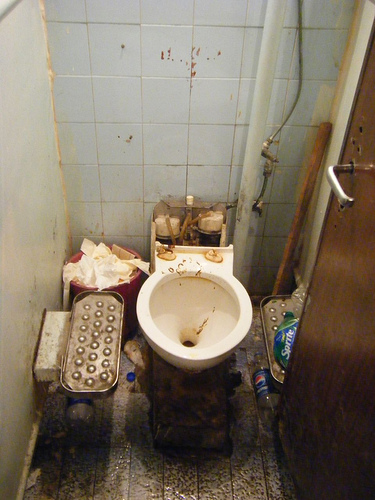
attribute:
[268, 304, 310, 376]
sprite bottle — empty 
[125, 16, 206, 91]
wall tile — old , dirty 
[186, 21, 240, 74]
wall tile — old , dirty 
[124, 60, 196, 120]
tile — old and dirty wall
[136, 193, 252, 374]
toilet — broken, white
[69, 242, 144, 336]
trash can — full, red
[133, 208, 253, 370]
toilet — dirty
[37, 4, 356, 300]
wall — tile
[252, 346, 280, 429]
pepsi bottle — empty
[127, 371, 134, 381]
bottle top — blue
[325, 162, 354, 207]
handle — silver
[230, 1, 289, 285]
pipe — white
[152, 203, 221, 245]
inside — exposed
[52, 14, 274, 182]
wall — old, dirty, tiled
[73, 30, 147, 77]
tile — old, dirty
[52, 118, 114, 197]
tile — dirty, old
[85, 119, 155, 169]
tile — old, dirty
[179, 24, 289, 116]
tile — dirty, old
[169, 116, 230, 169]
tile — old, dirty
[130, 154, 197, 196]
tile — dirty, old